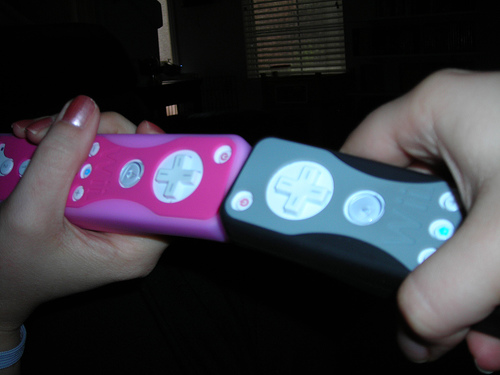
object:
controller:
[1, 128, 254, 243]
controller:
[217, 134, 500, 296]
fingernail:
[55, 93, 97, 135]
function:
[150, 147, 203, 204]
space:
[22, 240, 499, 374]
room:
[0, 1, 499, 374]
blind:
[237, 1, 351, 78]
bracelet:
[0, 321, 29, 373]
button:
[262, 158, 334, 221]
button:
[228, 186, 254, 211]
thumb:
[391, 174, 500, 360]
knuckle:
[390, 269, 455, 339]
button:
[427, 219, 457, 240]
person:
[0, 95, 179, 374]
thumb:
[2, 96, 98, 255]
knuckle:
[19, 135, 82, 187]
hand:
[0, 92, 175, 297]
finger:
[116, 121, 173, 282]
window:
[230, 1, 357, 84]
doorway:
[146, 1, 195, 133]